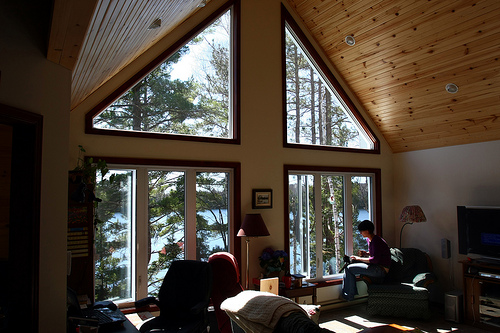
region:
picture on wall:
[250, 188, 273, 208]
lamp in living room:
[237, 212, 269, 291]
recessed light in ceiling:
[342, 32, 357, 48]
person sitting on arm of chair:
[341, 219, 392, 302]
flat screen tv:
[462, 203, 499, 259]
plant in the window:
[71, 148, 108, 236]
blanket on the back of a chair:
[220, 289, 300, 329]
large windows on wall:
[87, 0, 388, 287]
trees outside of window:
[151, 75, 226, 129]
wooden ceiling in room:
[290, 3, 499, 123]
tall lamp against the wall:
[231, 208, 271, 291]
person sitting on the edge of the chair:
[326, 213, 396, 298]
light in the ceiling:
[439, 73, 467, 104]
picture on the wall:
[247, 178, 278, 212]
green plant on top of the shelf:
[74, 149, 106, 217]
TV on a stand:
[451, 202, 496, 257]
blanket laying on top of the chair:
[211, 292, 320, 329]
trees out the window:
[136, 74, 223, 134]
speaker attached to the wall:
[431, 226, 455, 274]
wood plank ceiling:
[369, 9, 476, 70]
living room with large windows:
[3, 0, 498, 330]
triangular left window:
[85, 0, 242, 140]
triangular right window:
[277, 0, 383, 156]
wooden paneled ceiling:
[291, 0, 498, 157]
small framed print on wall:
[251, 186, 274, 210]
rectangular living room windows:
[81, 152, 243, 319]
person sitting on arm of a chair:
[339, 219, 394, 304]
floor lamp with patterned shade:
[394, 201, 436, 248]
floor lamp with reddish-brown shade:
[234, 212, 272, 297]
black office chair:
[135, 258, 212, 331]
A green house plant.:
[70, 143, 118, 205]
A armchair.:
[352, 243, 439, 322]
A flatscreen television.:
[462, 207, 499, 269]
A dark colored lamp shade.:
[234, 212, 271, 237]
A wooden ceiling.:
[54, 3, 499, 155]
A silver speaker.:
[445, 285, 463, 323]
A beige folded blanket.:
[219, 287, 311, 331]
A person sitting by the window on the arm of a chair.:
[330, 204, 396, 307]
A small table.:
[264, 279, 319, 309]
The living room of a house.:
[64, 22, 493, 332]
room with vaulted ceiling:
[1, 0, 498, 332]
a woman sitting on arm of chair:
[341, 223, 395, 304]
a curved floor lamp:
[391, 201, 428, 247]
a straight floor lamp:
[237, 212, 271, 295]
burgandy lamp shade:
[238, 211, 269, 235]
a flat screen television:
[458, 207, 499, 257]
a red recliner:
[208, 250, 262, 330]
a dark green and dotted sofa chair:
[364, 246, 435, 320]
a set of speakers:
[436, 238, 463, 324]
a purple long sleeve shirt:
[363, 234, 393, 264]